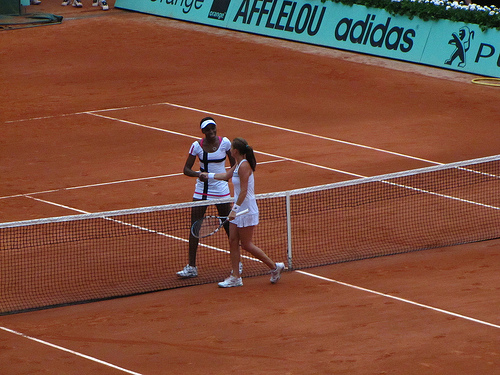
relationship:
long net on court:
[68, 124, 481, 326] [9, 17, 470, 357]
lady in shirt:
[217, 138, 286, 291] [231, 160, 258, 211]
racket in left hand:
[188, 207, 251, 241] [224, 207, 241, 223]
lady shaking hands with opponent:
[176, 113, 239, 278] [213, 131, 281, 283]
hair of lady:
[228, 140, 262, 174] [217, 138, 286, 291]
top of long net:
[5, 155, 495, 227] [0, 154, 499, 317]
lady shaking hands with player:
[176, 113, 239, 278] [221, 136, 286, 288]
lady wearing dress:
[228, 127, 294, 274] [214, 158, 276, 266]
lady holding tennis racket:
[217, 138, 286, 291] [187, 204, 260, 240]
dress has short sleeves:
[187, 135, 240, 201] [181, 138, 237, 168]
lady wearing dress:
[168, 112, 238, 279] [187, 135, 240, 201]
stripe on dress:
[196, 146, 213, 205] [179, 135, 241, 201]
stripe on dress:
[196, 146, 213, 205] [191, 150, 229, 194]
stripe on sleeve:
[188, 144, 194, 156] [186, 140, 200, 155]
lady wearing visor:
[176, 113, 239, 278] [198, 113, 240, 138]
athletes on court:
[176, 114, 288, 283] [11, 14, 498, 372]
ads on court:
[330, 11, 498, 78] [0, 0, 499, 375]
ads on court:
[144, 2, 326, 39] [0, 0, 499, 375]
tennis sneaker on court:
[174, 260, 201, 279] [11, 14, 498, 372]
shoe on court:
[219, 272, 250, 289] [11, 14, 498, 372]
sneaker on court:
[264, 258, 286, 285] [11, 14, 498, 372]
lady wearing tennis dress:
[176, 113, 239, 278] [188, 137, 234, 202]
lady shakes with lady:
[176, 113, 239, 278] [217, 138, 286, 291]